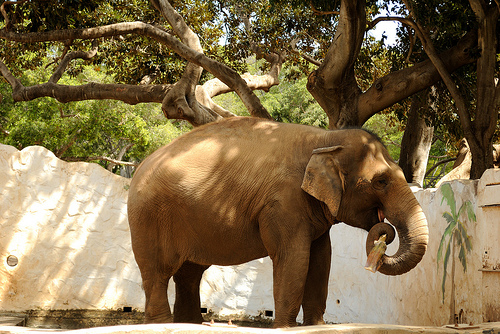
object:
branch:
[1, 48, 195, 121]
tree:
[0, 3, 500, 180]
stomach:
[164, 137, 274, 255]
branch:
[364, 232, 387, 272]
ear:
[297, 145, 345, 218]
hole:
[264, 310, 275, 318]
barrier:
[1, 141, 497, 328]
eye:
[378, 179, 385, 185]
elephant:
[126, 115, 429, 327]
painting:
[435, 182, 479, 323]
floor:
[2, 319, 495, 334]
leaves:
[68, 111, 124, 128]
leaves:
[280, 86, 298, 103]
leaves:
[136, 60, 171, 70]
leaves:
[433, 110, 450, 130]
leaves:
[272, 15, 299, 34]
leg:
[301, 227, 331, 316]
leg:
[272, 238, 313, 327]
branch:
[285, 19, 430, 115]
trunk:
[363, 180, 429, 278]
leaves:
[70, 118, 91, 137]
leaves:
[262, 2, 330, 31]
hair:
[336, 126, 388, 146]